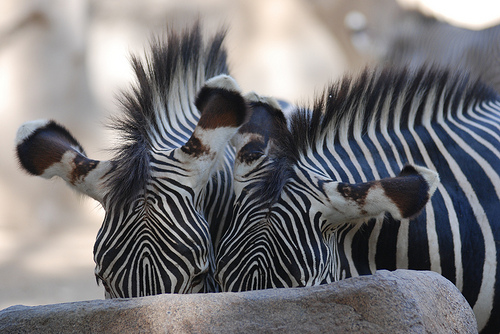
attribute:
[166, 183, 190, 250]
stripe — black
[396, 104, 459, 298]
stripe — black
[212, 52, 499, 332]
zebra — eating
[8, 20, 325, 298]
zebra — black and white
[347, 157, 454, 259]
ear — pointy, black and white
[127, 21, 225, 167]
fur — black and white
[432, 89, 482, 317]
stripe — black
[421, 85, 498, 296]
stripe — black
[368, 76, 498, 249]
fur — stripes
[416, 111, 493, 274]
fur — stripes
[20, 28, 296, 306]
zebra — black and white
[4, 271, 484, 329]
rock — gray